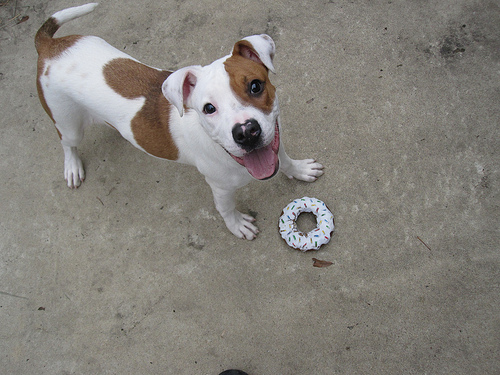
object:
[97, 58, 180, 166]
spots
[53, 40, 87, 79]
fur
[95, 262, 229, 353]
part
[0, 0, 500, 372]
ground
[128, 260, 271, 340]
surface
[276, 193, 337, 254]
donut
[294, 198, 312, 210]
frosting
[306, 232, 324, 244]
frosting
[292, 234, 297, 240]
sprinkles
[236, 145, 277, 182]
tongue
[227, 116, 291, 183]
mouth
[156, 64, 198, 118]
ears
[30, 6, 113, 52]
tail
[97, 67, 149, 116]
fur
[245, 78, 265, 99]
eye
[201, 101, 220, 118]
eye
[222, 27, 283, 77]
ear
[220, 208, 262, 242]
paw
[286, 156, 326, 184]
paw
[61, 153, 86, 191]
paw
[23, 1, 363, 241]
dog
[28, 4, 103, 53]
tail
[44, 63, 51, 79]
spot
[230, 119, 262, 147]
nose